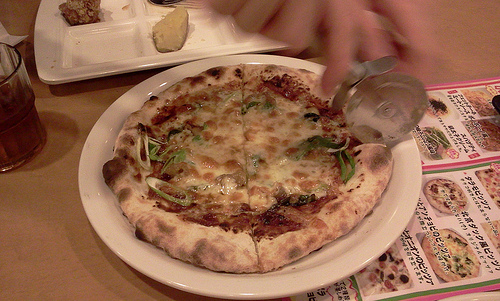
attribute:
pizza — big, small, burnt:
[102, 62, 394, 273]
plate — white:
[77, 53, 425, 300]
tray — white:
[33, 0, 312, 84]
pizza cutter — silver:
[310, 38, 428, 147]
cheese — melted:
[146, 79, 351, 236]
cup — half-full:
[0, 41, 47, 174]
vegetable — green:
[338, 148, 356, 183]